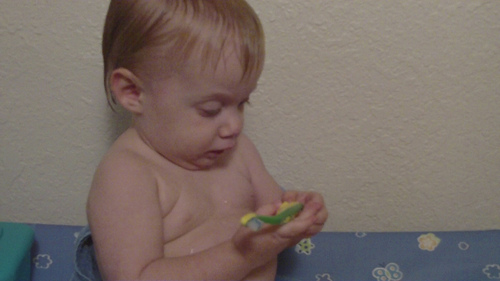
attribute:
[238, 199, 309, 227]
toothbrush — white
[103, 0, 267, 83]
hair — freshly, wet, blonde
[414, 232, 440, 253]
flower — small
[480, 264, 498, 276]
flower — yellow, small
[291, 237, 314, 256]
flower — white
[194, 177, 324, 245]
toothbrush — white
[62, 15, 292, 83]
hair — blonde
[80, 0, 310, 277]
baby — chubby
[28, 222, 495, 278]
bumper — white, blue, padded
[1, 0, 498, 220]
wall — white